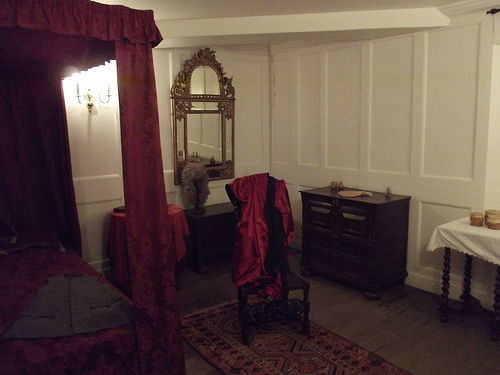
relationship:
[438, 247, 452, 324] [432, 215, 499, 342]
leg on table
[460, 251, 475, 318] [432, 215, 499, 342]
leg on table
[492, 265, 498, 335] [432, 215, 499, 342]
leg on table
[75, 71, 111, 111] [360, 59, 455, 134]
candlestick on wall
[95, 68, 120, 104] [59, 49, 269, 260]
light on wall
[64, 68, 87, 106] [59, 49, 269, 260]
light on wall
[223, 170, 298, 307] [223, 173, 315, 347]
clothing on chair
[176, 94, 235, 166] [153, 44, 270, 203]
mirror on wall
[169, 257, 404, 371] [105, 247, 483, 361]
carpet on ground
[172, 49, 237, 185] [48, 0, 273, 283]
mirror on wall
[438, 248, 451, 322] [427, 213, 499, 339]
stick on table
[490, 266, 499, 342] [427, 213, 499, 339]
stick on table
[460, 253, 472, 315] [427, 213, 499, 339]
stick on table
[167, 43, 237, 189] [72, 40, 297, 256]
mirror on wall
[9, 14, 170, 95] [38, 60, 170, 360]
canopy over bed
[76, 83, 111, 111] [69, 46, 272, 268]
candlestick on wall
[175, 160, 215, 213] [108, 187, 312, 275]
wig on top of dresser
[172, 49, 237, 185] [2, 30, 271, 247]
mirror on wall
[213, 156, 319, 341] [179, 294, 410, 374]
chair on carpet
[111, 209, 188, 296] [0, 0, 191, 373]
cloth matches bed dressings